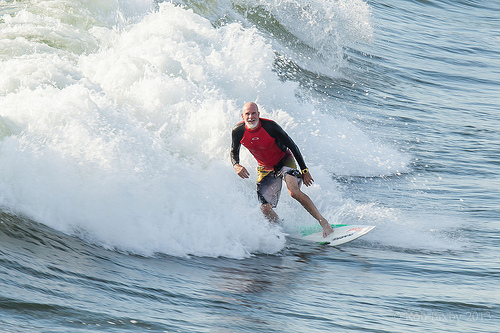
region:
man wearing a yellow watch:
[293, 162, 331, 180]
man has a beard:
[224, 93, 275, 138]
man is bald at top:
[223, 91, 281, 113]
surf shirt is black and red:
[229, 119, 303, 154]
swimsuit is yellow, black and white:
[223, 157, 333, 200]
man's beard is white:
[237, 114, 274, 138]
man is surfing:
[201, 101, 371, 269]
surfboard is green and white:
[286, 215, 397, 254]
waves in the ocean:
[105, 1, 452, 298]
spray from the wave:
[308, 5, 460, 227]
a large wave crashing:
[36, 4, 420, 281]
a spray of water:
[313, 81, 440, 210]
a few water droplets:
[365, 129, 445, 219]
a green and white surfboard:
[285, 207, 381, 254]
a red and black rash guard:
[221, 115, 316, 186]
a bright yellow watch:
[296, 167, 313, 177]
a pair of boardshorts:
[246, 149, 313, 214]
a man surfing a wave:
[176, 79, 378, 264]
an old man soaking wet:
[210, 86, 339, 245]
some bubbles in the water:
[79, 297, 144, 331]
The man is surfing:
[208, 94, 374, 270]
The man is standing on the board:
[221, 96, 356, 251]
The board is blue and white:
[276, 201, 383, 265]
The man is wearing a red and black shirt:
[221, 91, 319, 214]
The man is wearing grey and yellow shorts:
[243, 153, 329, 223]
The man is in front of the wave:
[193, 96, 374, 260]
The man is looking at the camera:
[223, 92, 328, 222]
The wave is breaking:
[26, 8, 432, 291]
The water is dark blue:
[368, 76, 475, 238]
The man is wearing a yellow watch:
[293, 156, 326, 199]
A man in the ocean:
[145, 55, 435, 300]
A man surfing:
[190, 65, 395, 280]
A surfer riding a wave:
[185, 60, 400, 295]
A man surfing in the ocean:
[130, 50, 435, 295]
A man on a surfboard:
[210, 65, 390, 275]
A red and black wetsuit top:
[220, 120, 315, 176]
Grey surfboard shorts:
[240, 155, 305, 210]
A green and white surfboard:
[280, 210, 380, 255]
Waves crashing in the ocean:
[20, 15, 490, 315]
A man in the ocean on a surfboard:
[2, 0, 494, 330]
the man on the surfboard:
[208, 90, 375, 257]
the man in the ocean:
[210, 98, 407, 279]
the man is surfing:
[218, 74, 374, 258]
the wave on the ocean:
[7, 0, 363, 265]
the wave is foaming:
[15, 5, 367, 277]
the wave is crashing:
[5, 1, 416, 263]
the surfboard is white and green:
[255, 211, 387, 254]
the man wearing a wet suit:
[211, 97, 363, 252]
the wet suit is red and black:
[228, 110, 318, 207]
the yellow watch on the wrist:
[298, 163, 316, 177]